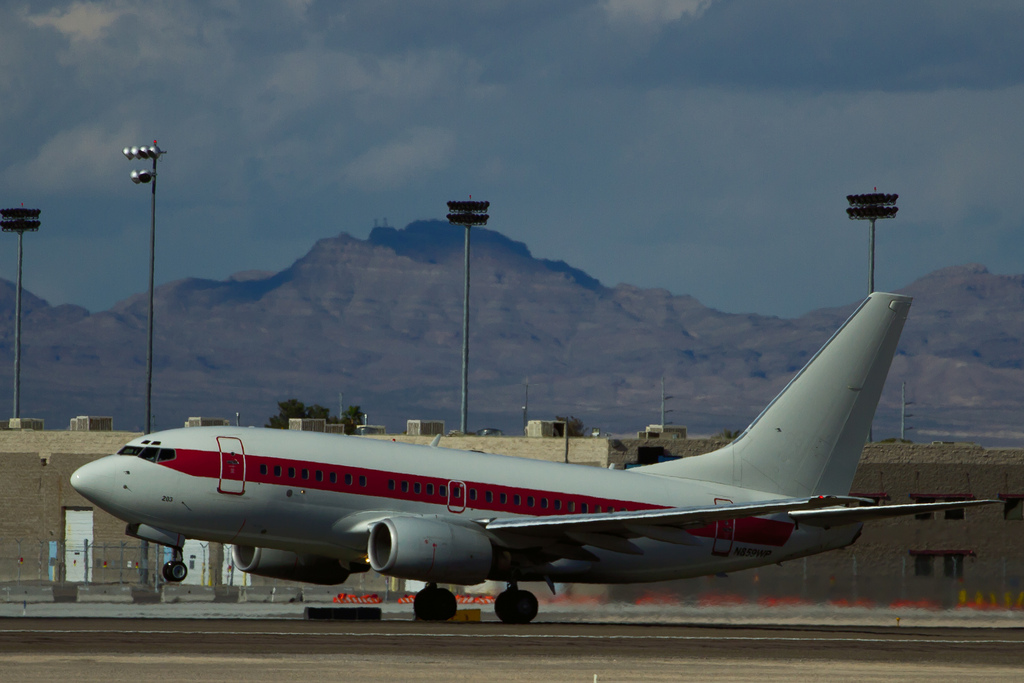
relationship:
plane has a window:
[71, 291, 995, 580] [256, 447, 272, 482]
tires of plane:
[411, 585, 461, 623] [63, 286, 992, 624]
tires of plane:
[411, 587, 457, 623] [63, 286, 992, 624]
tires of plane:
[397, 573, 461, 628] [63, 286, 992, 624]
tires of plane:
[485, 581, 548, 628] [67, 297, 983, 669]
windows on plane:
[291, 456, 348, 491] [63, 286, 992, 624]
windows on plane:
[247, 446, 324, 498] [51, 255, 965, 666]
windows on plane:
[497, 489, 554, 513] [58, 303, 990, 595]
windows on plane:
[476, 482, 538, 508] [67, 297, 983, 669]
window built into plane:
[274, 463, 287, 479] [63, 286, 992, 624]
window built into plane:
[287, 463, 296, 477] [63, 286, 992, 624]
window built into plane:
[298, 460, 308, 481] [63, 286, 992, 624]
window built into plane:
[313, 465, 327, 483] [63, 286, 992, 624]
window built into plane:
[351, 462, 370, 491] [63, 286, 992, 624]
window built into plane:
[384, 473, 398, 497] [63, 286, 992, 624]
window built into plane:
[387, 473, 413, 497] [63, 286, 992, 624]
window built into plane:
[409, 473, 426, 492] [63, 286, 992, 624]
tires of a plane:
[485, 581, 548, 628] [67, 297, 983, 669]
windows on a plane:
[490, 489, 563, 516] [15, 325, 906, 615]